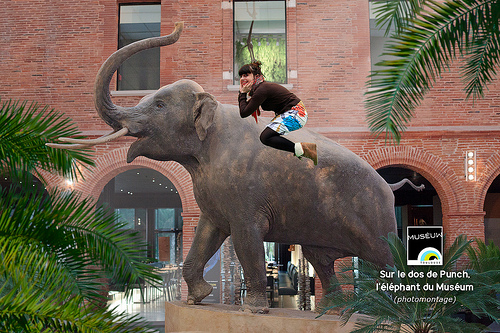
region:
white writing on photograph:
[352, 261, 497, 315]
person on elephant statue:
[190, 30, 358, 190]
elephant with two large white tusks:
[27, 72, 211, 164]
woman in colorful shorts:
[237, 58, 319, 158]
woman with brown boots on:
[288, 140, 323, 170]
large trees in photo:
[0, 97, 142, 329]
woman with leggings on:
[250, 102, 342, 200]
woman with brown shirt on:
[232, 54, 306, 131]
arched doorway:
[70, 155, 218, 285]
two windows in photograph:
[90, 17, 328, 119]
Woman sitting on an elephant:
[143, 56, 331, 175]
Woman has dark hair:
[228, 49, 274, 81]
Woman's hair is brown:
[230, 52, 282, 78]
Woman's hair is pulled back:
[234, 55, 280, 82]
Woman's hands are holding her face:
[233, 63, 275, 103]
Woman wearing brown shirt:
[226, 81, 313, 117]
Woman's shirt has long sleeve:
[232, 79, 307, 124]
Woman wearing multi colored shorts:
[258, 94, 315, 136]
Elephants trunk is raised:
[83, 9, 194, 141]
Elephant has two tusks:
[45, 115, 136, 157]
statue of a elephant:
[99, 25, 429, 307]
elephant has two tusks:
[24, 118, 156, 159]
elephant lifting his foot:
[160, 259, 229, 314]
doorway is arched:
[90, 150, 206, 332]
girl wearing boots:
[285, 132, 345, 184]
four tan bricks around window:
[217, 2, 309, 81]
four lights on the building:
[456, 145, 486, 193]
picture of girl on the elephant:
[238, 50, 331, 157]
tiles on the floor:
[125, 295, 160, 312]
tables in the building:
[133, 233, 181, 301]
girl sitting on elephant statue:
[230, 61, 325, 181]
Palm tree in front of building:
[6, 95, 93, 331]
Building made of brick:
[311, 32, 358, 145]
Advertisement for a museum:
[366, 211, 491, 312]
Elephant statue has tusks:
[30, 76, 190, 169]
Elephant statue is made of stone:
[188, 177, 402, 299]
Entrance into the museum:
[81, 160, 191, 292]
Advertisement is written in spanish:
[370, 260, 478, 315]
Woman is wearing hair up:
[230, 55, 276, 95]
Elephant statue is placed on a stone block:
[145, 286, 306, 331]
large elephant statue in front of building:
[83, 33, 443, 324]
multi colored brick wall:
[296, 10, 372, 91]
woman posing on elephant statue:
[227, 59, 334, 172]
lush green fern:
[13, 176, 104, 318]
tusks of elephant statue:
[36, 120, 156, 159]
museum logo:
[371, 213, 495, 314]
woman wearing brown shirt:
[220, 55, 325, 176]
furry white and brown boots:
[287, 135, 327, 167]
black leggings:
[255, 127, 311, 164]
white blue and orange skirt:
[268, 96, 313, 142]